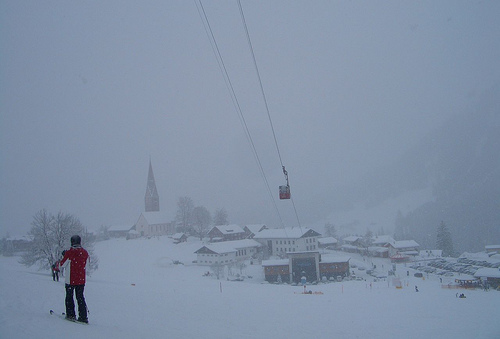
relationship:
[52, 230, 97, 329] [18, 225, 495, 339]
person skiing on snow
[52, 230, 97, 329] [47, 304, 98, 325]
person on skies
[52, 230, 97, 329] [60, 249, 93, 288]
person wearing jacket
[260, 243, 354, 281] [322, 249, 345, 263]
building with roof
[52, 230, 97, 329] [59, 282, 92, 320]
person has legs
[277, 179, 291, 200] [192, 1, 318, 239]
carriage on power lines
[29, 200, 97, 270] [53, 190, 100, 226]
tree covered in snow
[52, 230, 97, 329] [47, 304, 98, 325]
person wearing skies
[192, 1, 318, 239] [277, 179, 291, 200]
power lines for carriage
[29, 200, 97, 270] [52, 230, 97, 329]
tree behind person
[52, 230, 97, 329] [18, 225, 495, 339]
person on top of snow